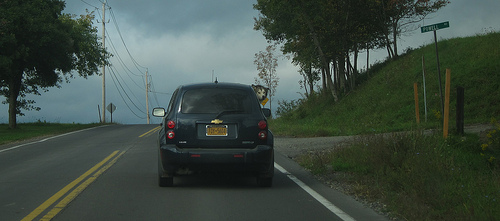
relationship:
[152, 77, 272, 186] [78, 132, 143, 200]
car on a road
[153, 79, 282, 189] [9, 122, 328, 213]
car on road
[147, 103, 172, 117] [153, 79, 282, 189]
mirror on car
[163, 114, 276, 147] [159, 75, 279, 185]
lights on car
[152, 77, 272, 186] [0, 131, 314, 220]
car on road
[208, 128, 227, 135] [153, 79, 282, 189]
license plate on car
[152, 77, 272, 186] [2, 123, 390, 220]
car on road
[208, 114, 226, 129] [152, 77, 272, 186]
logo on car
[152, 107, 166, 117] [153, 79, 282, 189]
mirror on car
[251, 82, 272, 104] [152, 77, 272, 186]
dog hanging out of car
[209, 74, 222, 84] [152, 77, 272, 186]
antennae on car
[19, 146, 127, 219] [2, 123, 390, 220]
line on road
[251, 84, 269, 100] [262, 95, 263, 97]
dog has nose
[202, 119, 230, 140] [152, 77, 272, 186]
license plate on car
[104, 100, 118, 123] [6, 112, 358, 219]
sign near road